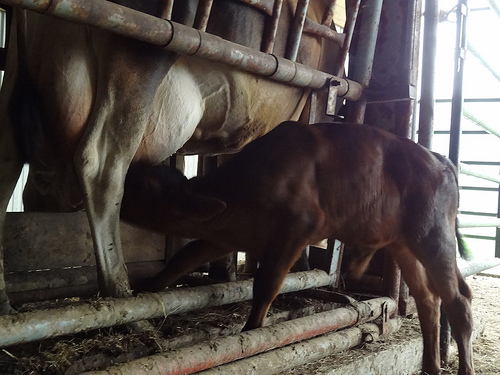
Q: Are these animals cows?
A: Yes, all the animals are cows.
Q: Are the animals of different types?
A: No, all the animals are cows.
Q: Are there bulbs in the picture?
A: No, there are no bulbs.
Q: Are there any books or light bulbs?
A: No, there are no light bulbs or books.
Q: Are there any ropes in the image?
A: No, there are no ropes.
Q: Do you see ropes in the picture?
A: No, there are no ropes.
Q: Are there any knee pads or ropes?
A: No, there are no ropes or knee pads.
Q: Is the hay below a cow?
A: Yes, the hay is below a cow.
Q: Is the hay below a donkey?
A: No, the hay is below a cow.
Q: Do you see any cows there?
A: Yes, there is a cow.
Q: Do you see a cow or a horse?
A: Yes, there is a cow.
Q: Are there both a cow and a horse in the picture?
A: No, there is a cow but no horses.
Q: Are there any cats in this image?
A: No, there are no cats.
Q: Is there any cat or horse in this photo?
A: No, there are no cats or horses.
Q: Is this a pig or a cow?
A: This is a cow.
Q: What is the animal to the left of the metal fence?
A: The animal is a cow.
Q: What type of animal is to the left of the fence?
A: The animal is a cow.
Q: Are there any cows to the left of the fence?
A: Yes, there is a cow to the left of the fence.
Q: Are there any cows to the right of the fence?
A: No, the cow is to the left of the fence.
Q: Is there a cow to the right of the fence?
A: No, the cow is to the left of the fence.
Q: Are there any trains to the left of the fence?
A: No, there is a cow to the left of the fence.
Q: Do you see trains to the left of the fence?
A: No, there is a cow to the left of the fence.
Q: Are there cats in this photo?
A: No, there are no cats.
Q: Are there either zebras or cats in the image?
A: No, there are no cats or zebras.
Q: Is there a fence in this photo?
A: Yes, there is a fence.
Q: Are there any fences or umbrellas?
A: Yes, there is a fence.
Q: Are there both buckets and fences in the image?
A: No, there is a fence but no buckets.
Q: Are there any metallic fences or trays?
A: Yes, there is a metal fence.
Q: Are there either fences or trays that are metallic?
A: Yes, the fence is metallic.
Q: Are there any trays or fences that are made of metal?
A: Yes, the fence is made of metal.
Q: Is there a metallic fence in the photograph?
A: Yes, there is a metal fence.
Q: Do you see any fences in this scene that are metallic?
A: Yes, there is a fence that is metallic.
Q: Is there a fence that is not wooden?
A: Yes, there is a metallic fence.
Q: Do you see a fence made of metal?
A: Yes, there is a fence that is made of metal.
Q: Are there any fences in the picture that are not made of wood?
A: Yes, there is a fence that is made of metal.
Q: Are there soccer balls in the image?
A: No, there are no soccer balls.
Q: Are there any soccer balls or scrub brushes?
A: No, there are no soccer balls or scrub brushes.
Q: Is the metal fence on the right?
A: Yes, the fence is on the right of the image.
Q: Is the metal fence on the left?
A: No, the fence is on the right of the image.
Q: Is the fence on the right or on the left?
A: The fence is on the right of the image.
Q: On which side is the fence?
A: The fence is on the right of the image.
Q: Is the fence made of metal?
A: Yes, the fence is made of metal.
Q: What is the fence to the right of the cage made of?
A: The fence is made of metal.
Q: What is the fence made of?
A: The fence is made of metal.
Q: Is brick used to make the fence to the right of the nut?
A: No, the fence is made of metal.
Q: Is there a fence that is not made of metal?
A: No, there is a fence but it is made of metal.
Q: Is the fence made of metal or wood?
A: The fence is made of metal.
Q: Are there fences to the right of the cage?
A: Yes, there is a fence to the right of the cage.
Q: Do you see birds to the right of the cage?
A: No, there is a fence to the right of the cage.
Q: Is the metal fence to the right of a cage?
A: Yes, the fence is to the right of a cage.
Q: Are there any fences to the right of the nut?
A: Yes, there is a fence to the right of the nut.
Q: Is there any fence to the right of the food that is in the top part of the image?
A: Yes, there is a fence to the right of the nut.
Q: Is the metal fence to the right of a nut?
A: Yes, the fence is to the right of a nut.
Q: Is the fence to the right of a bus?
A: No, the fence is to the right of a nut.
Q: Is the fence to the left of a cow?
A: No, the fence is to the right of a cow.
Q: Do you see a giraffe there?
A: No, there are no giraffes.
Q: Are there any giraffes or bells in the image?
A: No, there are no giraffes or bells.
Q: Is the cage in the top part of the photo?
A: Yes, the cage is in the top of the image.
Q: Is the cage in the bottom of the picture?
A: No, the cage is in the top of the image.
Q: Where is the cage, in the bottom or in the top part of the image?
A: The cage is in the top of the image.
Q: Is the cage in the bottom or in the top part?
A: The cage is in the top of the image.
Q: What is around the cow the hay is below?
A: The cage is around the cow.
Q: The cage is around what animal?
A: The cage is around the cow.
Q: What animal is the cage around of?
A: The cage is around the cow.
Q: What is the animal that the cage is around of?
A: The animal is a cow.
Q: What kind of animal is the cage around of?
A: The cage is around the cow.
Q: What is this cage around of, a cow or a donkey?
A: The cage is around a cow.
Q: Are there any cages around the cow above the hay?
A: Yes, there is a cage around the cow.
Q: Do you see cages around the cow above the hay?
A: Yes, there is a cage around the cow.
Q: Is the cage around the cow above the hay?
A: Yes, the cage is around the cow.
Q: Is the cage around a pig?
A: No, the cage is around the cow.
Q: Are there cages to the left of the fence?
A: Yes, there is a cage to the left of the fence.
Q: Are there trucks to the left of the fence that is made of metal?
A: No, there is a cage to the left of the fence.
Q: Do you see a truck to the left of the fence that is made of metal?
A: No, there is a cage to the left of the fence.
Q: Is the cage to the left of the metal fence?
A: Yes, the cage is to the left of the fence.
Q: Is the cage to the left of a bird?
A: No, the cage is to the left of the fence.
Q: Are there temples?
A: No, there are no temples.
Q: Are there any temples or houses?
A: No, there are no temples or houses.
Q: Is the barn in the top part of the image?
A: Yes, the barn is in the top of the image.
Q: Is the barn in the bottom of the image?
A: No, the barn is in the top of the image.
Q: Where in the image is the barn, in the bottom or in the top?
A: The barn is in the top of the image.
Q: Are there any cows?
A: Yes, there is a cow.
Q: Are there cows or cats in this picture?
A: Yes, there is a cow.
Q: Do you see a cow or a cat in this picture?
A: Yes, there is a cow.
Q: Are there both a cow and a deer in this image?
A: No, there is a cow but no deer.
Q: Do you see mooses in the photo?
A: No, there are no mooses.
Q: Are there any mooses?
A: No, there are no mooses.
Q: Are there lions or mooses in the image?
A: No, there are no mooses or lions.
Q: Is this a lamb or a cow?
A: This is a cow.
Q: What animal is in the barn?
A: The cow is in the barn.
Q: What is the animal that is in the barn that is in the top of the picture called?
A: The animal is a cow.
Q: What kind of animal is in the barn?
A: The animal is a cow.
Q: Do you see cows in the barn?
A: Yes, there is a cow in the barn.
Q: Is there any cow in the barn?
A: Yes, there is a cow in the barn.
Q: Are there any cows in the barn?
A: Yes, there is a cow in the barn.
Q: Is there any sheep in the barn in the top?
A: No, there is a cow in the barn.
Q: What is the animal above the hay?
A: The animal is a cow.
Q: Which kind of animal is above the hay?
A: The animal is a cow.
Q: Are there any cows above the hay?
A: Yes, there is a cow above the hay.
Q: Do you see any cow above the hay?
A: Yes, there is a cow above the hay.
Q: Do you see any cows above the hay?
A: Yes, there is a cow above the hay.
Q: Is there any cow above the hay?
A: Yes, there is a cow above the hay.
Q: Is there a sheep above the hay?
A: No, there is a cow above the hay.